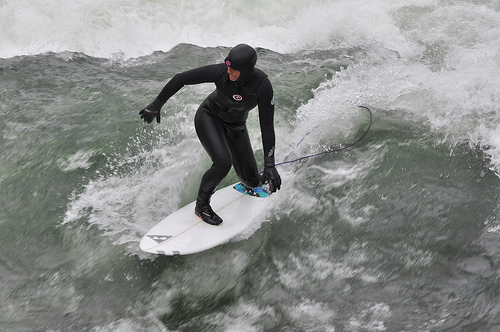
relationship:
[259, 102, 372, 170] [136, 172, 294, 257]
rope of board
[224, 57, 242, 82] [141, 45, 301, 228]
face on person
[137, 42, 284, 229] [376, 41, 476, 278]
person in ocean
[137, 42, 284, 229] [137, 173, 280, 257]
person on surfboard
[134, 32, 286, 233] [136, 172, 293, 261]
person on surfboard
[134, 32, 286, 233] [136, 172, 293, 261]
person riding on surfboard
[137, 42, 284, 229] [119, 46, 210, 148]
person has arm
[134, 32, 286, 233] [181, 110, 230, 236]
person has leg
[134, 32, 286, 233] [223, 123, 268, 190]
person has leg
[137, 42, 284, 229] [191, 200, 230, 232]
person has foot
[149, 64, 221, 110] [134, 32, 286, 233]
arm of a person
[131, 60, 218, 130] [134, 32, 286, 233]
arm of a person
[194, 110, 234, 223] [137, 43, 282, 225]
leg on a person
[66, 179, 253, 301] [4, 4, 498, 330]
waves on ocean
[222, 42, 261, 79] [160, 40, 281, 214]
head is on person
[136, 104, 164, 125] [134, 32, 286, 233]
hand is on person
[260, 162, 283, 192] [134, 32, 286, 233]
hand is on person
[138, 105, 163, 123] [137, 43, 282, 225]
hand is on person